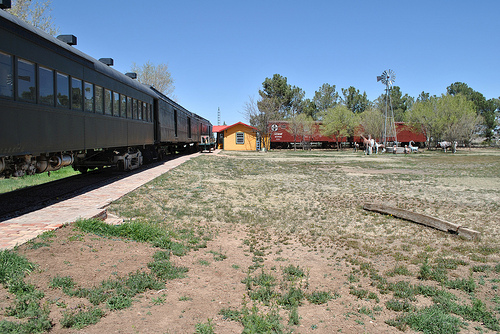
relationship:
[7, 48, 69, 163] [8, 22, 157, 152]
window on train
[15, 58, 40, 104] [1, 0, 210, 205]
window on train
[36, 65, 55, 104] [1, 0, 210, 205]
window on train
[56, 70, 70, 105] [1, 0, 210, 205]
window on train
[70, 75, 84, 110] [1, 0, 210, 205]
window on train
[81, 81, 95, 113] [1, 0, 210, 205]
window on train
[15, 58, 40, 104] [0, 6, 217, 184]
window on train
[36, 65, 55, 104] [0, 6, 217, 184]
window on train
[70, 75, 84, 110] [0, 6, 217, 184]
window on train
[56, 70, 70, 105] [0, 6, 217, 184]
window on train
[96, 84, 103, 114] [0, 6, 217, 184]
window on train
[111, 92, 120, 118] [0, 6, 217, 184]
window on train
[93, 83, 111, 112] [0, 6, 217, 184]
window on train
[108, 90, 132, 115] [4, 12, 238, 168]
glass window on train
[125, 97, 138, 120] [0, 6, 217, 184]
window on train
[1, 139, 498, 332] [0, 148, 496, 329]
sand on ground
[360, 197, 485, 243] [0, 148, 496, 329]
object on ground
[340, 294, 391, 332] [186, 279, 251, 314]
pebbles on ground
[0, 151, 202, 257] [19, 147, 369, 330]
path on ground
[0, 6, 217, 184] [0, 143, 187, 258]
train on track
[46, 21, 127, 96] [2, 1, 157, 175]
boxes on top of car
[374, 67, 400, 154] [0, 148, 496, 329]
weather vane on ground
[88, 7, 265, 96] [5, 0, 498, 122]
clouds in sky